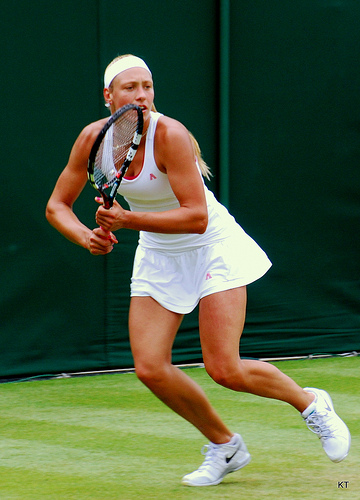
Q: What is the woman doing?
A: Standing.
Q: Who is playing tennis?
A: A woman.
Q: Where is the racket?
A: Woman's hands.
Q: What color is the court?
A: Green.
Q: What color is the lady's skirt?
A: White.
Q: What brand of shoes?
A: Nike.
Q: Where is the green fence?
A: Behind the lady.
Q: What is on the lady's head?
A: A headband.